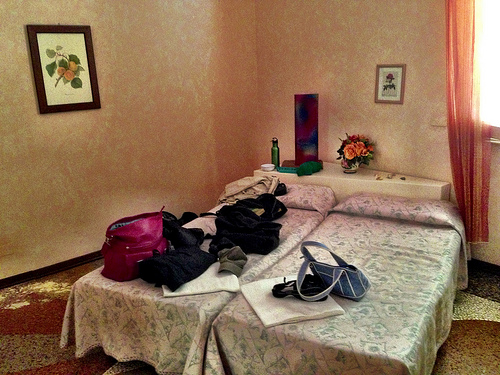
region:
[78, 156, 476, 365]
Two twin beds pushed together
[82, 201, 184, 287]
A red tote bag on the bed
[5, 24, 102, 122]
A picture of flowers on the wall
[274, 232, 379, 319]
A ladies bag that is blue and white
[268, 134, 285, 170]
A green glass bottle on the headboard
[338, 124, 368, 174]
A vase holding peach colored flowers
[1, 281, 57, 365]
The floor has a design painted on it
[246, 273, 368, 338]
A qhite towl folded on the bed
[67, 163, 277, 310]
Lots of items thrown on the bed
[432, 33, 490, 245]
The curtain is orange in color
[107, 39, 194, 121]
The wallpaper has a pattern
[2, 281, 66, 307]
Powder on the ground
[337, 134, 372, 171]
The flowers are pink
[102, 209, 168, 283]
The bag is pink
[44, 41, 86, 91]
Picture of some oranges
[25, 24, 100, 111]
Picture frame is dark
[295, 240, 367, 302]
Purse is blue and white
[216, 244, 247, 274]
The hat is green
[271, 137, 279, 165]
The bottle is green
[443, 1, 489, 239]
The drapes are pink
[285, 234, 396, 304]
blue on the table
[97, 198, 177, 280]
purple purse on a table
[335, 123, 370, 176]
orange flowers in vase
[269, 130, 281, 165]
green water bottle on back of bed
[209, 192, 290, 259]
black bag on bed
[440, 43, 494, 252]
orange curtain on window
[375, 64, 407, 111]
picture on the wall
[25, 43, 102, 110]
picture on the wall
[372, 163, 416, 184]
rocks on the back of bed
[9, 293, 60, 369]
carpet on the bedroom floor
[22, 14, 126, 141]
picture is on wall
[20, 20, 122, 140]
the plant is in picture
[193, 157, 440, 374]
two beds are twin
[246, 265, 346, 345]
the towel is white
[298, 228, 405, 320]
purse is on the bed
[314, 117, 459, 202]
flower is on the headboard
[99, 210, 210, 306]
the bag is open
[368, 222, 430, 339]
the design is on bedspread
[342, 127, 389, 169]
the flowers are pink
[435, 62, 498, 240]
the curtains are sheer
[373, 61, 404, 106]
A picture on the wall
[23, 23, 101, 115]
A picture on the wall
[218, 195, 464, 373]
A twin size bed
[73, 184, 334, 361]
A twin size bed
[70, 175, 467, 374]
A pair of twin beds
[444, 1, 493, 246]
Some red curtains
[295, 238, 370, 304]
A denim bag on the bed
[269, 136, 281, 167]
A green water bottle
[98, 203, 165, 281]
A pink bag on the bed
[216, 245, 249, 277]
A hat on the bed